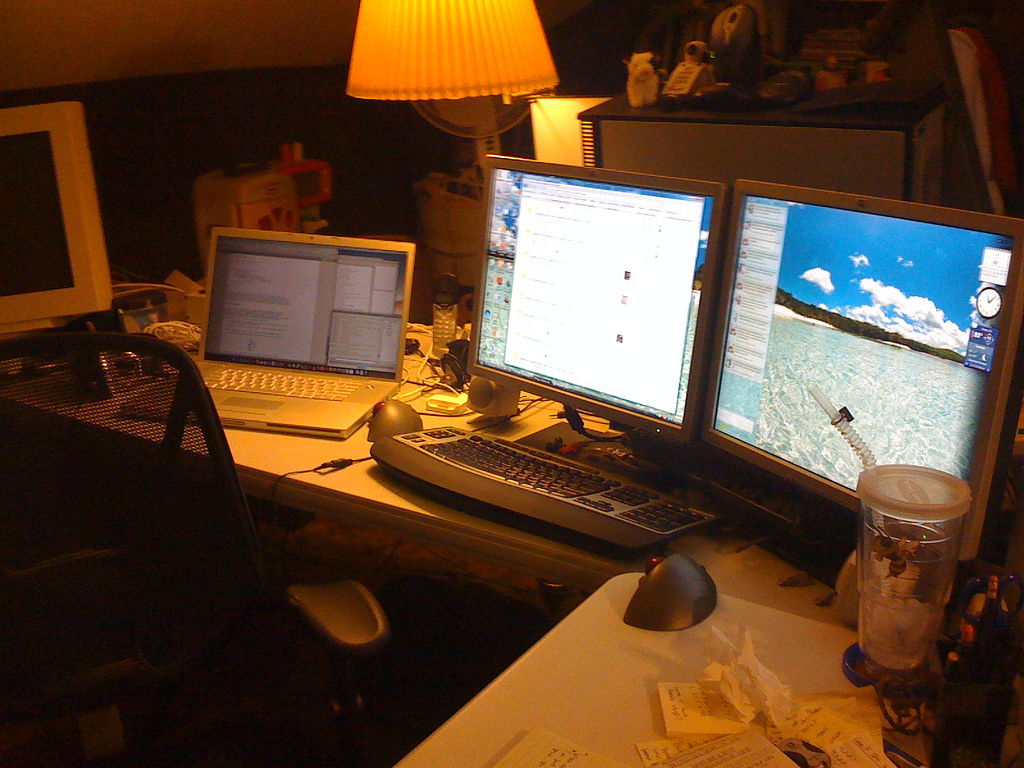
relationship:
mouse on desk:
[624, 554, 713, 624] [43, 340, 1014, 757]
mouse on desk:
[371, 396, 423, 440] [2, 294, 860, 625]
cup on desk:
[806, 387, 975, 679] [350, 566, 1022, 759]